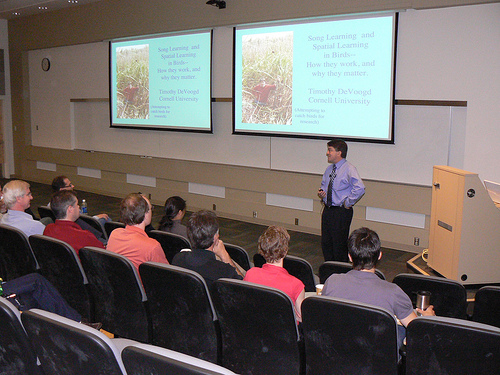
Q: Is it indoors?
A: Yes, it is indoors.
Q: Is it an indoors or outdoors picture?
A: It is indoors.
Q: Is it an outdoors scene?
A: No, it is indoors.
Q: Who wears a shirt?
A: The man wears a shirt.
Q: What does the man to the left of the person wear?
A: The man wears a shirt.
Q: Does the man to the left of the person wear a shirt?
A: Yes, the man wears a shirt.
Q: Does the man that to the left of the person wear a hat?
A: No, the man wears a shirt.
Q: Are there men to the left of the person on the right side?
A: Yes, there is a man to the left of the person.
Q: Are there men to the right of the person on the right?
A: No, the man is to the left of the person.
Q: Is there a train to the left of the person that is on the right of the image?
A: No, there is a man to the left of the person.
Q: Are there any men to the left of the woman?
A: Yes, there is a man to the left of the woman.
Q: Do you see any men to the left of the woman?
A: Yes, there is a man to the left of the woman.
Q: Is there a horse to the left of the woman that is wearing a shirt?
A: No, there is a man to the left of the woman.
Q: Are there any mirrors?
A: No, there are no mirrors.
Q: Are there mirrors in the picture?
A: No, there are no mirrors.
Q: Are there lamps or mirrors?
A: No, there are no mirrors or lamps.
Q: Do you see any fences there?
A: No, there are no fences.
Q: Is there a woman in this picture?
A: Yes, there is a woman.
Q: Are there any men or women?
A: Yes, there is a woman.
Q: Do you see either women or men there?
A: Yes, there is a woman.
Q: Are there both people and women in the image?
A: Yes, there are both a woman and people.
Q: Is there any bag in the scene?
A: No, there are no bags.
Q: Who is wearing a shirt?
A: The woman is wearing a shirt.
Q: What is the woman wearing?
A: The woman is wearing a shirt.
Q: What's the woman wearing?
A: The woman is wearing a shirt.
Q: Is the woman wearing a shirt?
A: Yes, the woman is wearing a shirt.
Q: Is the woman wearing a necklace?
A: No, the woman is wearing a shirt.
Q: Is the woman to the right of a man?
A: Yes, the woman is to the right of a man.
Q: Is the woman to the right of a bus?
A: No, the woman is to the right of a man.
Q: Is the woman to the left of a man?
A: No, the woman is to the right of a man.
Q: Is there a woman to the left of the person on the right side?
A: Yes, there is a woman to the left of the person.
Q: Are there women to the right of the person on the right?
A: No, the woman is to the left of the person.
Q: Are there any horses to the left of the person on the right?
A: No, there is a woman to the left of the person.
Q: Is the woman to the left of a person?
A: Yes, the woman is to the left of a person.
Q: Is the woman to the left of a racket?
A: No, the woman is to the left of a person.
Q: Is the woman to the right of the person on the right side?
A: No, the woman is to the left of the person.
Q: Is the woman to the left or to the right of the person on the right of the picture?
A: The woman is to the left of the person.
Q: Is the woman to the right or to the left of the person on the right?
A: The woman is to the left of the person.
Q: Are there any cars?
A: No, there are no cars.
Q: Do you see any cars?
A: No, there are no cars.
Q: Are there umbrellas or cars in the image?
A: No, there are no cars or umbrellas.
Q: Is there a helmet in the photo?
A: No, there are no helmets.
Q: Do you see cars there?
A: No, there are no cars.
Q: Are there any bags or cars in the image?
A: No, there are no cars or bags.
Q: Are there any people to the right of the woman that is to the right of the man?
A: Yes, there is a person to the right of the woman.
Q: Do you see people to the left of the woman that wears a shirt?
A: No, the person is to the right of the woman.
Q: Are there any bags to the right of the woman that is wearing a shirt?
A: No, there is a person to the right of the woman.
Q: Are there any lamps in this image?
A: No, there are no lamps.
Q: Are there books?
A: No, there are no books.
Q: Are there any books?
A: No, there are no books.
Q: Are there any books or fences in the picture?
A: No, there are no books or fences.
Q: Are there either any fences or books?
A: No, there are no books or fences.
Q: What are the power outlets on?
A: The power outlets are on the wall.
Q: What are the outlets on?
A: The power outlets are on the wall.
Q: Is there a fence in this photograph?
A: No, there are no fences.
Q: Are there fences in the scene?
A: No, there are no fences.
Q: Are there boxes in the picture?
A: No, there are no boxes.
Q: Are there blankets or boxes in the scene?
A: No, there are no boxes or blankets.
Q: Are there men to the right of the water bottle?
A: Yes, there is a man to the right of the water bottle.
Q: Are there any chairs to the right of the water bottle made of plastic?
A: No, there is a man to the right of the water bottle.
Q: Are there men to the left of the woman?
A: Yes, there is a man to the left of the woman.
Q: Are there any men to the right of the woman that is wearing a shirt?
A: No, the man is to the left of the woman.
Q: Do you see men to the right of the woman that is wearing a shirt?
A: No, the man is to the left of the woman.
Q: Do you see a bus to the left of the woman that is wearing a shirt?
A: No, there is a man to the left of the woman.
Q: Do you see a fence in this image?
A: No, there are no fences.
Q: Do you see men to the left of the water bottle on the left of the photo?
A: Yes, there is a man to the left of the water bottle.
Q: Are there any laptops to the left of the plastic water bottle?
A: No, there is a man to the left of the water bottle.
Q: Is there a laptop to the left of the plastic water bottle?
A: No, there is a man to the left of the water bottle.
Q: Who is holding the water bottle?
A: The man is holding the water bottle.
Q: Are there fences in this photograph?
A: No, there are no fences.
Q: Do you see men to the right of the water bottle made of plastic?
A: Yes, there is a man to the right of the water bottle.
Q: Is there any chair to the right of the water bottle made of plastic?
A: No, there is a man to the right of the water bottle.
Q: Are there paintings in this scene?
A: No, there are no paintings.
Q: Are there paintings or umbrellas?
A: No, there are no paintings or umbrellas.